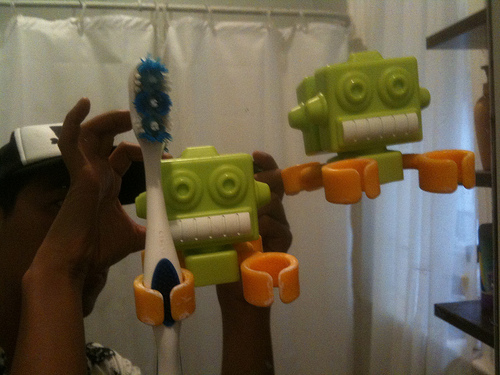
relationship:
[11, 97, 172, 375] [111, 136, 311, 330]
hand holding toy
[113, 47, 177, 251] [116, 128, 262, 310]
toothbrush and a toy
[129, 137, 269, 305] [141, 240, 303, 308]
toy with a holder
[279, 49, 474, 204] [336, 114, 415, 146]
toothbrush holder with teeth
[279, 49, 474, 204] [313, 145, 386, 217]
toothbrush holder with hand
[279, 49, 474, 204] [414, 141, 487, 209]
toothbrush holder with hand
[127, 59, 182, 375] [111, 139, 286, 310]
toothbrush held by toy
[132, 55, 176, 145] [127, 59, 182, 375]
bristles of toothbrush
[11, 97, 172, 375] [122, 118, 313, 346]
hand holding toy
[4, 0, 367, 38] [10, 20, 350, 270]
rail bar of curtain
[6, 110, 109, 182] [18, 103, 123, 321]
hat of boy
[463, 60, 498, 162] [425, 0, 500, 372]
bottle on shelf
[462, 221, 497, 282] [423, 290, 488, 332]
can on stand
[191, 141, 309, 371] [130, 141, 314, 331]
arm holding toy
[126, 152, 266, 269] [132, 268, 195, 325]
robot head with clip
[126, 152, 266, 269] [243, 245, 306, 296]
robot head with hand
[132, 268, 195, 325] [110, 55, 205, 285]
clip holding toothbrush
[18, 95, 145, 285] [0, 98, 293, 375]
hand on boy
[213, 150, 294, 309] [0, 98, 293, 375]
hand on boy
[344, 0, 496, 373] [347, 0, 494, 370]
curtain over window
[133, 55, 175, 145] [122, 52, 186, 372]
bristles on toothbrush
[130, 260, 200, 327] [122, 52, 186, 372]
clip holding toothbrush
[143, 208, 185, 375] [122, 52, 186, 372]
handle on toothbrush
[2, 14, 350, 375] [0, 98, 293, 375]
curtain behind boy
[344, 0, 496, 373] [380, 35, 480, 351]
curtain over window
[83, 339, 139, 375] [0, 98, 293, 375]
shirt on boy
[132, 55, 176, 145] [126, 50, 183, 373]
bristles on toothbrush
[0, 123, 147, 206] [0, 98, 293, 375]
hat on boy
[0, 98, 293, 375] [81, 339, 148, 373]
boy wearing shirt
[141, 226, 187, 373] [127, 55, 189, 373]
handle on toothbrush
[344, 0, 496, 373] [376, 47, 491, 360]
curtain on window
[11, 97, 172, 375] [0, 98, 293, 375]
hand on boy